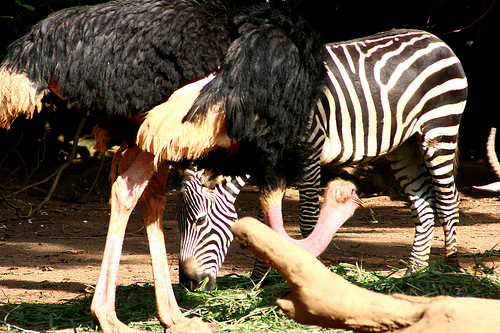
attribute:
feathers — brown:
[33, 19, 330, 161]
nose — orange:
[351, 195, 365, 209]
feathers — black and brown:
[6, 4, 327, 183]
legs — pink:
[80, 149, 190, 331]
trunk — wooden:
[227, 207, 432, 331]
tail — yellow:
[2, 63, 47, 132]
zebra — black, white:
[220, 20, 486, 262]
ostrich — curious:
[13, 8, 398, 330]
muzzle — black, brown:
[175, 257, 217, 289]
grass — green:
[29, 272, 483, 327]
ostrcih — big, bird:
[1, 5, 371, 330]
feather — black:
[67, 42, 85, 59]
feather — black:
[98, 12, 117, 35]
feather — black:
[141, 22, 162, 42]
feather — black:
[182, 68, 228, 126]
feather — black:
[260, 41, 290, 76]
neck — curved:
[255, 180, 328, 259]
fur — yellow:
[4, 72, 47, 126]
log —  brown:
[282, 304, 415, 323]